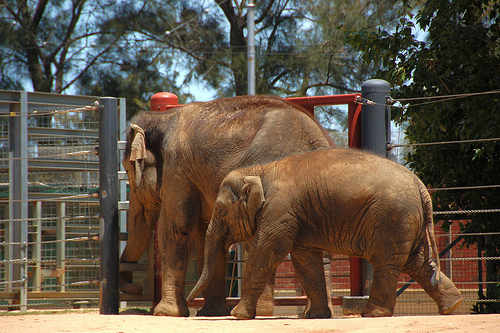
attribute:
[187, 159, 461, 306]
elephant — smaller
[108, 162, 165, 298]
trunk — grey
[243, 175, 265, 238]
ear — grey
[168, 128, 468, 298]
elephant — small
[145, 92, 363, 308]
gate — red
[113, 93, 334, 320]
elephant — large, larger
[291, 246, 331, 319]
leg — grey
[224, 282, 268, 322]
leg — grey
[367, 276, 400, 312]
leg — grey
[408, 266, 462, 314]
leg — grey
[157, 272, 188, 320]
leg — grey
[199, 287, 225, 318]
leg — grey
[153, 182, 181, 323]
leg — grey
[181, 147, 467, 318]
elephant — small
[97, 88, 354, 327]
elephant — large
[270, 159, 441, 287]
elephant — smaller